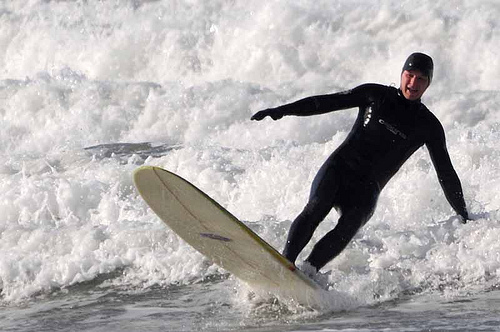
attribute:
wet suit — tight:
[276, 90, 460, 266]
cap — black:
[398, 52, 436, 79]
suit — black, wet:
[266, 57, 488, 311]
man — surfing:
[250, 47, 472, 284]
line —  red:
[153, 165, 279, 296]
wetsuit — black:
[284, 82, 467, 272]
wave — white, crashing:
[4, 73, 498, 165]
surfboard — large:
[110, 156, 373, 313]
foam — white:
[31, 62, 456, 239]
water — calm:
[0, 0, 498, 328]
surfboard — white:
[123, 152, 347, 309]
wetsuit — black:
[194, 37, 489, 287]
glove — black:
[251, 107, 283, 121]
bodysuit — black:
[279, 82, 464, 269]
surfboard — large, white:
[136, 160, 334, 318]